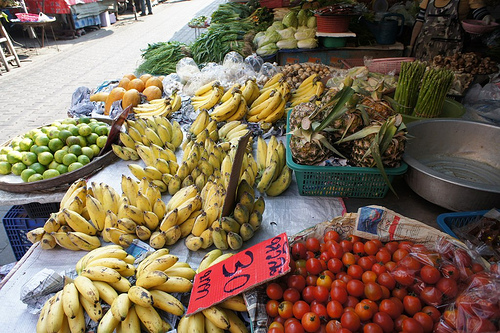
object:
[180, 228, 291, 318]
sign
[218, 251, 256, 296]
price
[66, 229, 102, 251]
bananas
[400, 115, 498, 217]
pan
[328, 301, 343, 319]
tomatoes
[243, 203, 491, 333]
newspaper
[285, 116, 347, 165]
pineapples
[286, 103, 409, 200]
display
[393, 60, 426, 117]
asparagus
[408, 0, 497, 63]
woman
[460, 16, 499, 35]
bowl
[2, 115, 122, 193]
tray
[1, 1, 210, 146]
street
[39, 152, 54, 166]
limes